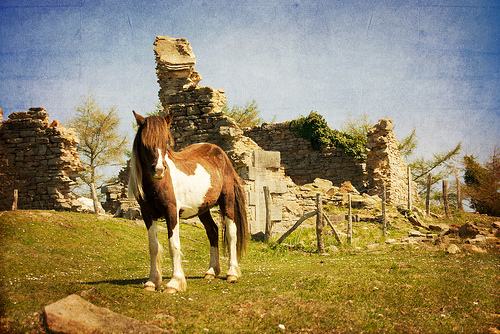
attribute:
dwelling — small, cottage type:
[154, 39, 431, 256]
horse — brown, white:
[115, 94, 288, 308]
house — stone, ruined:
[0, 34, 437, 240]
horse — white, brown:
[98, 107, 273, 292]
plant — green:
[335, 246, 424, 316]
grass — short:
[254, 248, 486, 333]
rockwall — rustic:
[4, 98, 88, 207]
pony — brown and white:
[128, 111, 248, 293]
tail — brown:
[216, 166, 248, 258]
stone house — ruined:
[9, 37, 417, 222]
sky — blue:
[378, 15, 495, 86]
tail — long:
[221, 174, 248, 261]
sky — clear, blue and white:
[298, 74, 348, 111]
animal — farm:
[57, 78, 303, 269]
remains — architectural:
[252, 68, 466, 258]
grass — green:
[237, 295, 320, 325]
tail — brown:
[213, 160, 266, 301]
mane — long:
[139, 112, 175, 152]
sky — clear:
[234, 10, 491, 124]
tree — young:
[276, 103, 383, 225]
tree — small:
[60, 87, 130, 220]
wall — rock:
[77, 117, 456, 237]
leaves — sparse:
[273, 263, 366, 280]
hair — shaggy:
[132, 120, 173, 150]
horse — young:
[117, 91, 306, 312]